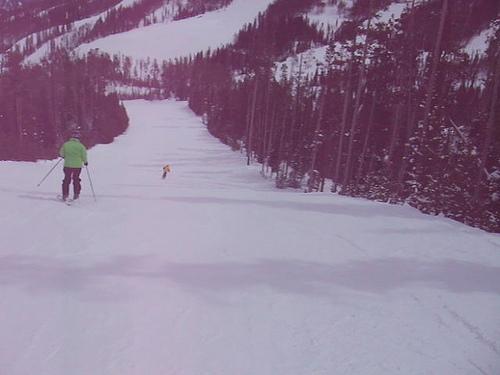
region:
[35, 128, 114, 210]
male snowboarding down hill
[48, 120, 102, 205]
snowboarder wearing a green jacket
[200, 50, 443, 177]
line of tall prickly trees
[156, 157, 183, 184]
snowboarder going downhill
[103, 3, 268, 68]
snow covered mountain slope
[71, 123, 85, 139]
snowboarder's back of head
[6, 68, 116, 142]
several prickly green trees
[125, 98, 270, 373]
smooth downward snow hill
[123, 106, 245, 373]
smooth snow path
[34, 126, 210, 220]
two snowboarders going downhill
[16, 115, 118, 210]
this is a person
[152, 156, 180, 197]
this is a person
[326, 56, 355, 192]
this is a tree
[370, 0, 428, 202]
this is a tree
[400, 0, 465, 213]
this is a tree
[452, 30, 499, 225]
this is a tree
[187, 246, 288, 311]
this is snow on the ground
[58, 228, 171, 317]
this is snow on the ground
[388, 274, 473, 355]
this is snow on the ground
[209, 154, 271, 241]
this is snow on the ground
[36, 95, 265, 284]
people skiing down mountain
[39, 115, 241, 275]
people skiing down slope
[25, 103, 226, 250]
skiiers going down mountain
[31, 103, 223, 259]
skiiers going down slope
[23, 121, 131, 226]
man holding skiis on slope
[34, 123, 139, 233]
skiier in green jacket and black pants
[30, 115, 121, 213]
male skiier in green jacket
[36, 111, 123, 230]
male skiier in black pants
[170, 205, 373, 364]
snow piled on mountain side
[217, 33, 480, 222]
trees lining snowy slope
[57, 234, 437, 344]
The snow is white and fluffy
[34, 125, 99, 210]
The man is skiing down the slopes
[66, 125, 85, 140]
The man is wearing a hat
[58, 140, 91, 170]
The man has on a green hat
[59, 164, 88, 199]
The man has on black pants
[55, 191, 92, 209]
The man is wearing skis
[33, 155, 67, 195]
The man has a ski stick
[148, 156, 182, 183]
The skier is down the slope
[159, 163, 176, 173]
The skier has a yellow jacket on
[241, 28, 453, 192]
The trees have no leaves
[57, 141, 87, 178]
the jacket is green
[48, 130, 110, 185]
the jacket is green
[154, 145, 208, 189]
the person is skiing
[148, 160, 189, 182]
the person is skiing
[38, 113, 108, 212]
the person is skiing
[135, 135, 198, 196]
the person is skiing